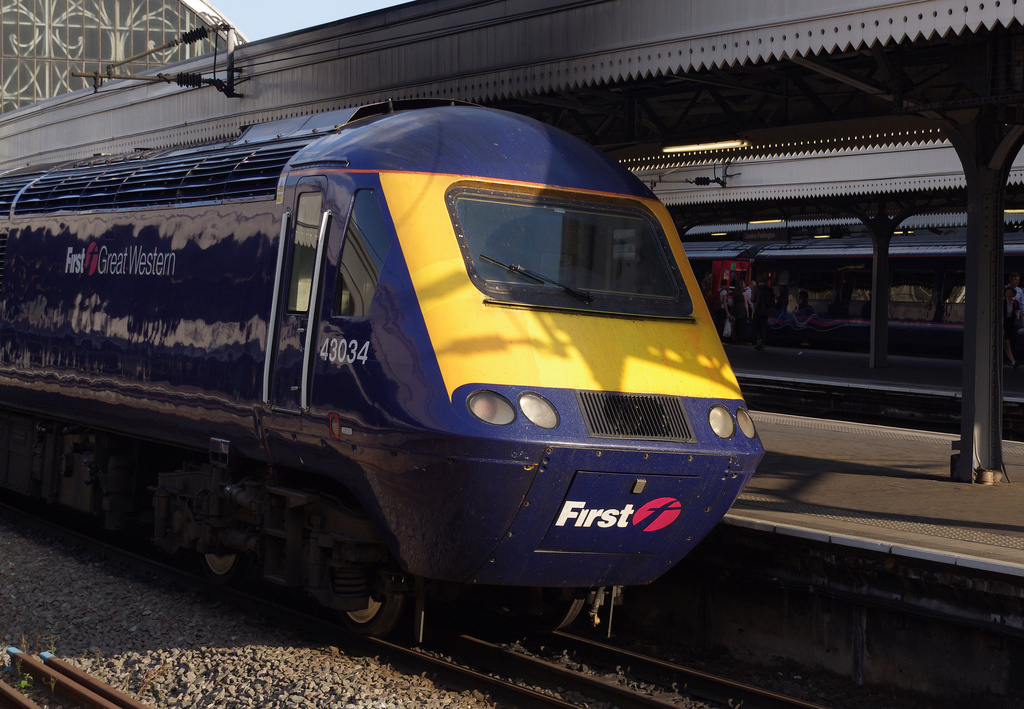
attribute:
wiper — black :
[486, 253, 692, 331]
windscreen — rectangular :
[458, 175, 694, 348]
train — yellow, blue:
[4, 93, 767, 634]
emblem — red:
[627, 485, 684, 537]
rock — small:
[222, 668, 236, 681]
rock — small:
[318, 679, 336, 692]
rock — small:
[160, 651, 180, 664]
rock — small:
[331, 659, 338, 668]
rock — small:
[104, 655, 126, 668]